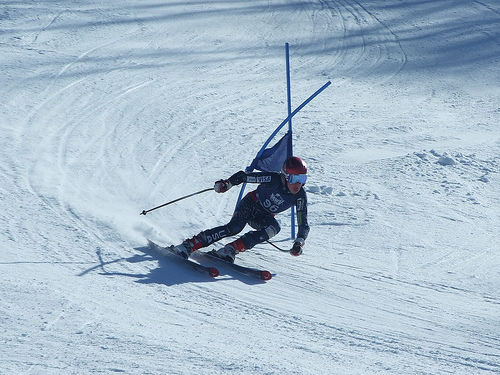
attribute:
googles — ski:
[276, 167, 311, 197]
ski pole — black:
[131, 181, 234, 230]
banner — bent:
[233, 41, 331, 239]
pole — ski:
[138, 187, 218, 214]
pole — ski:
[266, 236, 293, 254]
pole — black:
[134, 179, 226, 234]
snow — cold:
[339, 65, 481, 310]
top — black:
[234, 171, 317, 230]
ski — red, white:
[142, 239, 214, 277]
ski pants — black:
[182, 195, 281, 269]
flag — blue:
[247, 129, 292, 174]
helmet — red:
[275, 147, 325, 185]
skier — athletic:
[144, 133, 356, 318]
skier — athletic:
[155, 101, 320, 285]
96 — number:
[262, 196, 277, 213]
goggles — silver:
[280, 172, 307, 184]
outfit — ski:
[182, 169, 311, 251]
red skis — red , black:
[192, 249, 277, 281]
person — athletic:
[110, 107, 422, 362]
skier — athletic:
[205, 123, 328, 266]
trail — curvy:
[17, 4, 496, 366]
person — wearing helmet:
[178, 155, 310, 281]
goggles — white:
[284, 171, 306, 183]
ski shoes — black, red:
[144, 240, 270, 287]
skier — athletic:
[132, 124, 322, 293]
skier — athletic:
[170, 155, 311, 265]